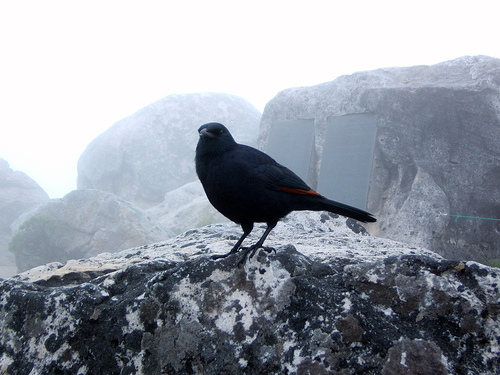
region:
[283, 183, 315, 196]
red feathers under the wind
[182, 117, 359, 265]
a black crow perched on boulder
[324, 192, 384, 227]
long black tail feathers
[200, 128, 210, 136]
a tiny black beak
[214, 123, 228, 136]
a round black eyes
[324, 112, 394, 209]
a gray plaque in the mountain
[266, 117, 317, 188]
a gray plaque in the mountain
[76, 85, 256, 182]
a large gray boulder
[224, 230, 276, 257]
skinny black bird legs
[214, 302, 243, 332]
a white patch on the rock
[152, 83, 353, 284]
the bird is black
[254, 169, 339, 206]
a line of red feather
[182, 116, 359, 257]
black bird on rock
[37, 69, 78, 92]
white clouds in blue sky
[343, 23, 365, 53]
white clouds in blue sky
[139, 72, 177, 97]
white clouds in blue sky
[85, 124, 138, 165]
white clouds in blue sky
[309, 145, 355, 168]
white clouds in blue sky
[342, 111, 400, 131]
white clouds in blue sky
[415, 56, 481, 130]
white clouds in blue sky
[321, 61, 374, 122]
white clouds in blue sky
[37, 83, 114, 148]
white clouds in blue sky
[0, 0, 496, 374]
bird sitting on rock surface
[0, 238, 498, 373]
white spots on the rocks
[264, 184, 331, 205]
orange part on feathers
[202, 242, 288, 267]
bird's feet are black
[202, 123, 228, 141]
bird's eye is black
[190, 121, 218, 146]
bird's beak is black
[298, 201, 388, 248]
bird's tail pointed outwards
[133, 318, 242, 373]
gray part of rock surface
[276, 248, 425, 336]
black part of rock surface